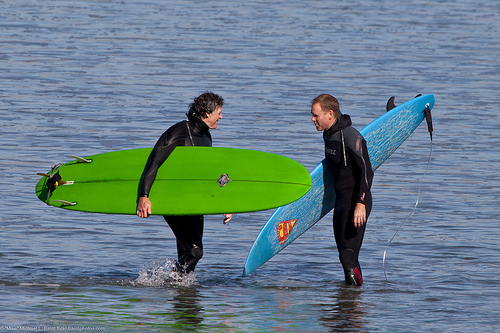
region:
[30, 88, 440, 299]
Two surfers holding their surfboards by the ocean shore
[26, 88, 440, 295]
Two surfers holding their surfboards by the ocean shore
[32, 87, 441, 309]
Two surfers holding their surfboards by the ocean shore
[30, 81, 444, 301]
Two surfers holding their surfboards by the ocean shore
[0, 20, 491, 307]
Some people are at the beach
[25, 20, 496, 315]
Some people are doing some surfing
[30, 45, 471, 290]
Some people are getting very wet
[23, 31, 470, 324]
Some people are wearing wetsuits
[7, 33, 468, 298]
Some people are in the water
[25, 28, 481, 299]
The men are having a discussion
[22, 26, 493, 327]
The men are talking about something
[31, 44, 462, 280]
Some people are enjoying the day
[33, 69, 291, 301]
this surfer has a green board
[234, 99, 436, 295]
the surfboard has a superman logo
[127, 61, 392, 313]
thse surfers are talking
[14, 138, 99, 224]
fins on the surfboard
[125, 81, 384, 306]
these surfers have on wet suits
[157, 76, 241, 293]
surfer with green board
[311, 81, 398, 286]
surfer with blue board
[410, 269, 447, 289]
ripples in the blue water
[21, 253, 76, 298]
ripples in the blue water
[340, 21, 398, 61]
ripples in the blue water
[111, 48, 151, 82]
ripples in the blue water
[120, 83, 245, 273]
surfer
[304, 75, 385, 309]
surfer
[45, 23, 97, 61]
ripples in the blue water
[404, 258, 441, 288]
ripples in the blue water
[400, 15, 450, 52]
ripples in the blue water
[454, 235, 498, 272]
ripples in the blue water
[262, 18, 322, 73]
ripples in the blue water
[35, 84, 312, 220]
a man holding a green surfboard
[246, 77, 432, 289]
a man holding a blue surf board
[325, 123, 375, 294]
a man wearing a black wet suit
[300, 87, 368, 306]
a man standing in water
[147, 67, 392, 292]
two men standing in water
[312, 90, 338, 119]
a man with short hair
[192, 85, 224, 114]
a man with black hair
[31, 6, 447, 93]
a large body of water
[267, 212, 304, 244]
a red and yellow design on a surfboard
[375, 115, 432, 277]
a rope attached to a surf board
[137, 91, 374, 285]
two men having a conversation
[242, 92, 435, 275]
a blue surfboard with black fins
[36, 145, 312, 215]
a bright green surfboard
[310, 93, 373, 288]
man wearing a black wet suit with red markings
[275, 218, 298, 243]
red and yellow Superman symbol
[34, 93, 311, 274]
surfer carrying a green board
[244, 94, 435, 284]
a surfer with a blue surfboard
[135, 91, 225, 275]
a man in a solid black wet suit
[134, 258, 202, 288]
water splashing up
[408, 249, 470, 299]
the small waves in the water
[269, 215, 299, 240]
logo on the board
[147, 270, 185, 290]
a splash of water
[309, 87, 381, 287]
the man is standing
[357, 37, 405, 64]
the water in the ocean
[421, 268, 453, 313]
the water is blue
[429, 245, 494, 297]
the blue water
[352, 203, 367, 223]
the mans hand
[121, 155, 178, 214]
man is holding a surfboard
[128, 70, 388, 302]
a pair of people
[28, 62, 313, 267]
man holding a surfboard